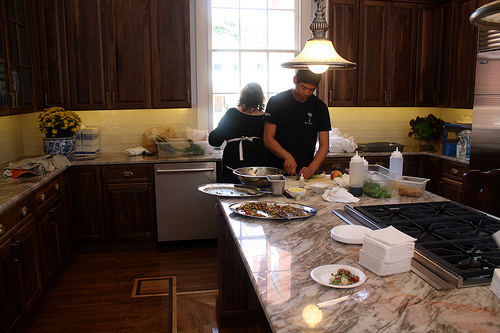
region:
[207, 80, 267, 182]
Woman in the kitchen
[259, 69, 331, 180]
Man in the kitchen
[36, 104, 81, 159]
Pot flower on the counter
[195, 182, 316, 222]
Metal trays on the counter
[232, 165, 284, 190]
Metal basin on the counter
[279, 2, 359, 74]
Light in the kitchen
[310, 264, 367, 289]
White plate on the counter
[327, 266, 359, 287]
Food on the plate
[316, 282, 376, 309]
Fork on the counter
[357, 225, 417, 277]
Napkins on the counter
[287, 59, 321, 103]
head of a person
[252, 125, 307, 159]
arm of a person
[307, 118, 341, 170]
arm of a person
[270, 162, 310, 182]
hand of a person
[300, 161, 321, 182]
hand of a person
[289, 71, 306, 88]
ear of a person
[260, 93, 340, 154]
body of a person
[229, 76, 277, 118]
head of a person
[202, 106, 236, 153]
arm of a person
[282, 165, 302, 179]
fingers of a person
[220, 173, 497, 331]
very large kitchen island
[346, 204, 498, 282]
black gas range on island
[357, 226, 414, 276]
stack of white napkins on island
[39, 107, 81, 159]
blue and white vase with yellow flowers on counter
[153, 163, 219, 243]
stainless steel dishwasher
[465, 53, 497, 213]
stainless steel refrigerator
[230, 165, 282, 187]
large metal mixing bowl on island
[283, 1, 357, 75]
light fixture over kitchen island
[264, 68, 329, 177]
man working at the island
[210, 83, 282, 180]
woman working by the window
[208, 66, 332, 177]
Man and woman in the kitchen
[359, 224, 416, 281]
Stack of napkins on the counter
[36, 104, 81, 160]
Yellow flowers in a planter on the counter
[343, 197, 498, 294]
Six-burner stove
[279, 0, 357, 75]
Lamp hanging from the ceiling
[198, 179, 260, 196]
Empty silver tray on the counter.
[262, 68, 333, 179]
Man slicing food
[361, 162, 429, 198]
Plastic containers of food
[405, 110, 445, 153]
Flowers on the counter.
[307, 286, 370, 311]
fork on the counter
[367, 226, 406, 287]
White napkins on the counter.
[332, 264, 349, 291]
Food on the plate.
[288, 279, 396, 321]
A fork on the counter.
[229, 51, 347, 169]
A man preparing food in the kitchen.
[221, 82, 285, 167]
A woman with her back turned.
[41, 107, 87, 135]
Yellow flowers in the vase.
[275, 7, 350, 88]
A lamp hanging from the ceiling.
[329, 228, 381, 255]
white plates on the counter.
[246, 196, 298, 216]
Food on the baking sheet.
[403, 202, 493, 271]
Burners on the stove.